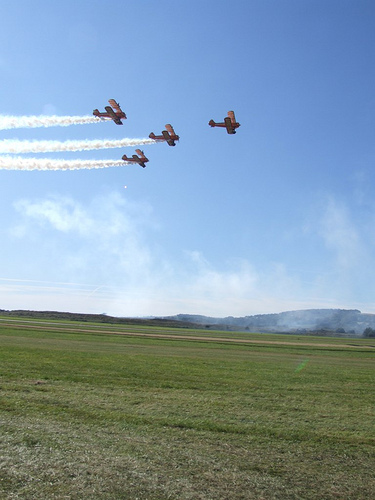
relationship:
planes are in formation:
[94, 93, 245, 173] [94, 96, 243, 171]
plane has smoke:
[92, 98, 128, 129] [0, 115, 153, 172]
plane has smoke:
[148, 122, 183, 151] [0, 115, 153, 172]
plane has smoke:
[120, 148, 149, 171] [1, 154, 137, 170]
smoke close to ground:
[0, 115, 153, 172] [3, 313, 370, 499]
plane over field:
[210, 107, 242, 136] [3, 313, 374, 497]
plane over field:
[148, 122, 183, 151] [3, 313, 374, 497]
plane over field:
[120, 148, 149, 171] [3, 313, 374, 497]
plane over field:
[92, 98, 128, 129] [3, 313, 374, 497]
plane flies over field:
[210, 107, 242, 136] [3, 313, 374, 497]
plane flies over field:
[148, 122, 183, 151] [3, 313, 374, 497]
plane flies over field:
[120, 148, 149, 171] [3, 313, 374, 497]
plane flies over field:
[92, 98, 128, 129] [3, 313, 374, 497]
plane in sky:
[210, 107, 242, 136] [4, 2, 374, 323]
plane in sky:
[148, 122, 183, 151] [4, 2, 374, 323]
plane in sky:
[92, 98, 128, 129] [4, 2, 374, 323]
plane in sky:
[120, 148, 149, 171] [4, 2, 374, 323]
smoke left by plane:
[0, 115, 153, 172] [92, 98, 128, 129]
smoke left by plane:
[0, 115, 153, 172] [148, 122, 183, 151]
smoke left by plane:
[1, 154, 137, 170] [120, 148, 149, 171]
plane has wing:
[92, 98, 128, 129] [108, 96, 127, 121]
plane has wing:
[92, 98, 128, 129] [103, 105, 122, 127]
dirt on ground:
[3, 317, 374, 354] [3, 313, 370, 499]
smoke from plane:
[0, 115, 153, 172] [92, 98, 128, 129]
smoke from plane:
[0, 115, 153, 172] [148, 122, 183, 151]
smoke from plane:
[1, 154, 137, 170] [120, 148, 149, 171]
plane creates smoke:
[148, 122, 183, 151] [0, 115, 153, 172]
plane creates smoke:
[120, 148, 149, 171] [1, 154, 137, 170]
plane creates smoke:
[92, 98, 128, 129] [0, 115, 153, 172]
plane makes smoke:
[92, 98, 128, 129] [0, 115, 153, 172]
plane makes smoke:
[148, 122, 183, 151] [0, 115, 153, 172]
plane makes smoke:
[120, 148, 149, 171] [1, 154, 137, 170]